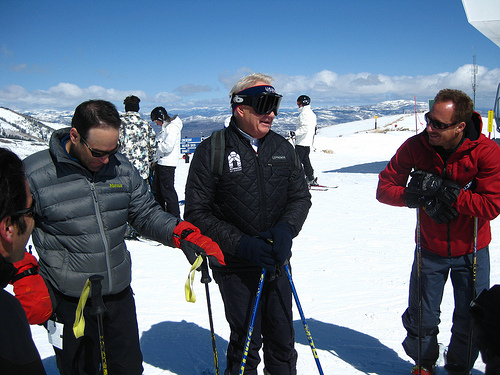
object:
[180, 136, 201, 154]
sign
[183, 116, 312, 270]
coat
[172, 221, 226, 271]
glove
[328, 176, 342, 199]
ground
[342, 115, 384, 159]
ground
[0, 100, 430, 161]
mountains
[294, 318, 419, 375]
shadow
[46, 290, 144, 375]
pants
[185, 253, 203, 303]
wrist traps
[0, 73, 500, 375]
man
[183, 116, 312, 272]
wearing coat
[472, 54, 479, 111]
tree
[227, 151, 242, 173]
logo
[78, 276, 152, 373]
poles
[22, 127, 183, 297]
jacket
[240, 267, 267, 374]
ski poles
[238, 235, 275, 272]
hand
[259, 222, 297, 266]
hand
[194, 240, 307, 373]
pants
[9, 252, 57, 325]
hand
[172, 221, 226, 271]
hand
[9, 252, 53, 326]
glove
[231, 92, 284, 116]
goggles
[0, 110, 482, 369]
slope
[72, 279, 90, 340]
loop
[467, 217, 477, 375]
ski poles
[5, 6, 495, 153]
distance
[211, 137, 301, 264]
part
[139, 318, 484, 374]
reflection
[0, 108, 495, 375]
ski slope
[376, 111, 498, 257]
coat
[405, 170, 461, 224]
gloves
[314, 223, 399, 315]
snow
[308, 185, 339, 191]
skis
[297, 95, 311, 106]
helmet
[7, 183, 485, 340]
ground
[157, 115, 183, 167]
coats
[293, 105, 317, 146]
coat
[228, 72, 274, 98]
hair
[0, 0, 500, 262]
background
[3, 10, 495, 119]
distance